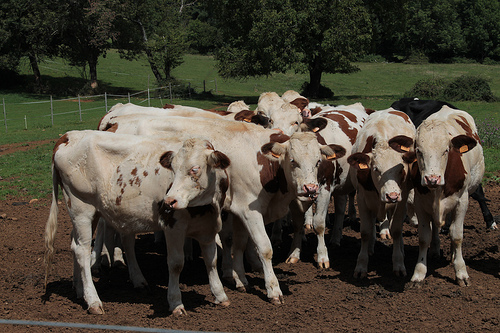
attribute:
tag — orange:
[458, 143, 469, 155]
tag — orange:
[401, 143, 411, 152]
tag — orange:
[359, 163, 371, 170]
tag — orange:
[325, 151, 337, 160]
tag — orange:
[312, 125, 321, 134]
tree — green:
[253, 0, 371, 100]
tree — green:
[116, 0, 207, 99]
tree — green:
[57, 0, 127, 91]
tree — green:
[0, 0, 67, 88]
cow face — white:
[157, 137, 231, 212]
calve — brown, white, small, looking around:
[40, 130, 231, 319]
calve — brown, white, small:
[102, 110, 347, 306]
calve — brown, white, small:
[346, 104, 418, 279]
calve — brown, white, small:
[385, 102, 487, 290]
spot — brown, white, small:
[130, 167, 140, 177]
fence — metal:
[0, 78, 217, 138]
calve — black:
[392, 94, 498, 231]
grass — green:
[0, 42, 500, 200]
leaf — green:
[328, 34, 335, 43]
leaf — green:
[246, 21, 259, 32]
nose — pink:
[163, 195, 177, 210]